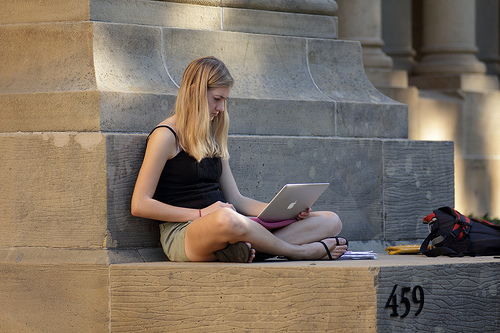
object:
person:
[131, 56, 350, 264]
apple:
[286, 200, 297, 210]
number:
[383, 285, 425, 319]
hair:
[172, 56, 234, 164]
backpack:
[418, 205, 500, 258]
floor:
[109, 255, 500, 272]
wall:
[83, 0, 455, 264]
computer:
[246, 182, 331, 223]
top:
[156, 148, 227, 209]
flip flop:
[213, 241, 251, 263]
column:
[337, 0, 486, 76]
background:
[0, 0, 499, 333]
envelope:
[338, 250, 379, 260]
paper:
[338, 250, 378, 260]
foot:
[213, 241, 256, 263]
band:
[199, 209, 202, 218]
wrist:
[202, 206, 213, 215]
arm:
[131, 134, 270, 222]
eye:
[213, 97, 221, 101]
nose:
[215, 100, 224, 112]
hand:
[203, 200, 236, 216]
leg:
[189, 206, 343, 261]